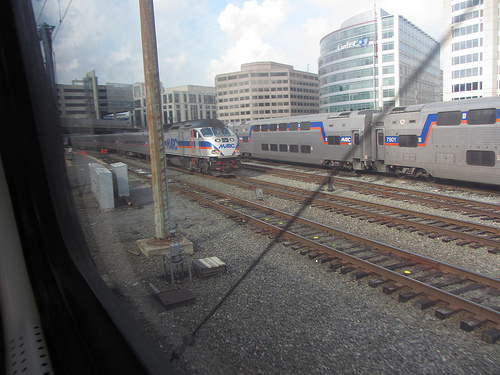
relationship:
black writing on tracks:
[215, 138, 235, 143] [76, 145, 500, 343]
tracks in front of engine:
[76, 145, 500, 343] [238, 92, 498, 194]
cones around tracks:
[96, 145, 111, 160] [76, 145, 500, 343]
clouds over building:
[31, 0, 442, 88] [443, 1, 498, 108]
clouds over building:
[31, 0, 442, 88] [318, 0, 442, 112]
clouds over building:
[31, 0, 442, 88] [212, 60, 320, 132]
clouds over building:
[31, 0, 442, 88] [133, 81, 217, 132]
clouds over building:
[31, 0, 442, 88] [55, 67, 134, 130]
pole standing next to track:
[137, 0, 170, 240] [89, 152, 499, 339]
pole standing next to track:
[137, 0, 170, 240] [113, 151, 497, 251]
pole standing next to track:
[137, 0, 170, 240] [237, 161, 485, 224]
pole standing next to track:
[137, 0, 170, 240] [240, 155, 484, 199]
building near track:
[443, 1, 498, 108] [234, 161, 497, 218]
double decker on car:
[242, 94, 485, 183] [230, 95, 500, 185]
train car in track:
[68, 119, 241, 178] [365, 215, 435, 322]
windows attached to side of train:
[250, 108, 480, 156] [228, 89, 498, 199]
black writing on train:
[216, 136, 232, 143] [258, 102, 491, 177]